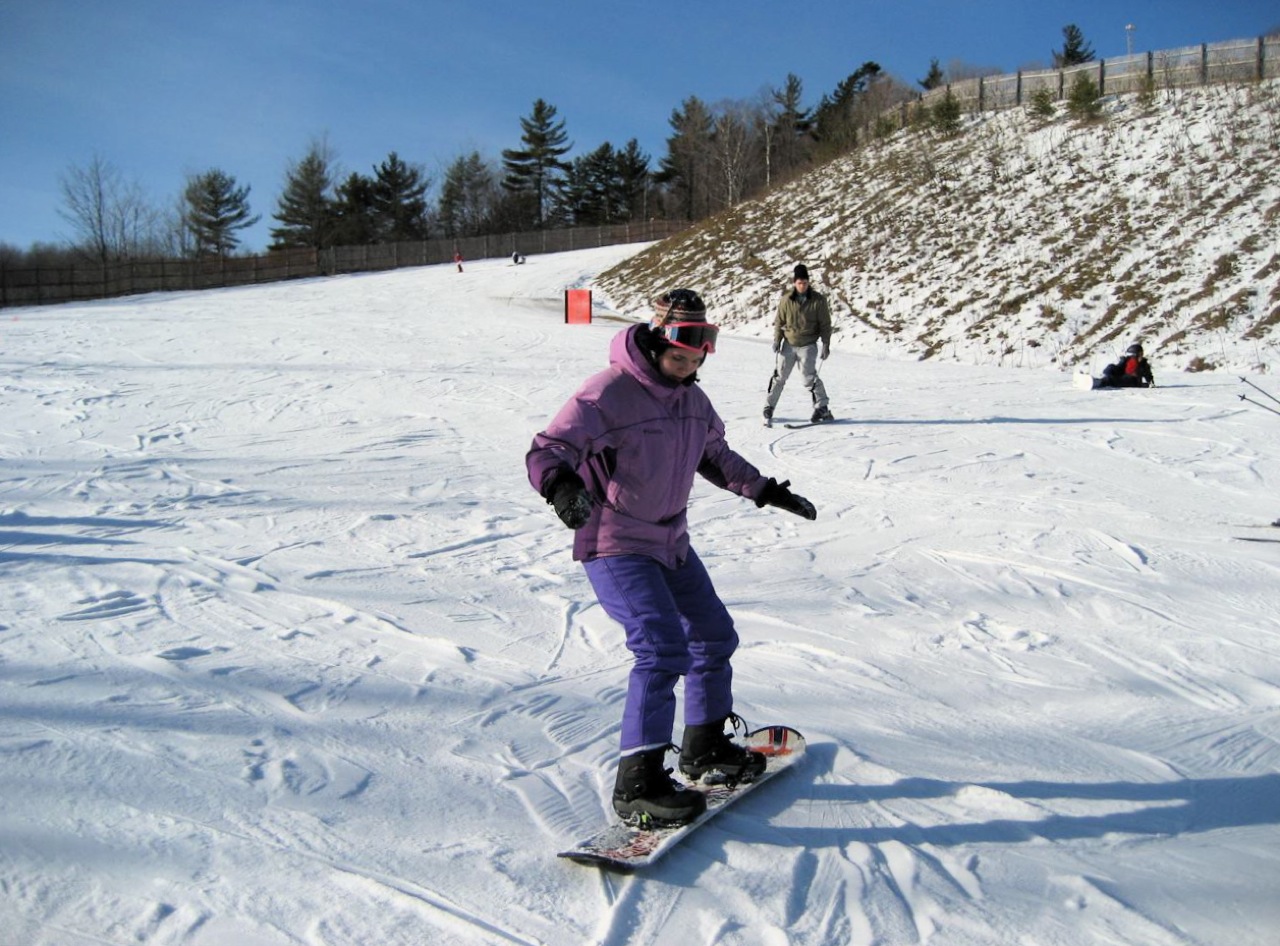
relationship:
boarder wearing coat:
[526, 289, 818, 868] [526, 323, 768, 571]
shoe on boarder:
[603, 747, 712, 826] [526, 289, 818, 868]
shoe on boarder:
[666, 712, 768, 784] [526, 289, 818, 868]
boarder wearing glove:
[526, 289, 818, 868] [729, 474, 831, 522]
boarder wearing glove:
[526, 289, 818, 868] [522, 460, 622, 536]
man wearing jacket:
[763, 264, 833, 429] [768, 286, 833, 348]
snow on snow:
[0, 239, 1280, 946] [0, 232, 1275, 937]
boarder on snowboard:
[526, 289, 818, 868] [561, 714, 805, 872]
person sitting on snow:
[1085, 316, 1168, 390] [0, 232, 1275, 937]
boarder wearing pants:
[526, 289, 818, 868] [587, 540, 740, 763]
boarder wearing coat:
[526, 289, 818, 868] [515, 318, 771, 569]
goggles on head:
[658, 325, 717, 351] [631, 286, 726, 379]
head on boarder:
[631, 286, 726, 379] [526, 289, 818, 868]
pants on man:
[764, 349, 836, 418] [750, 269, 861, 415]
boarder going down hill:
[503, 281, 849, 918] [852, 256, 1154, 884]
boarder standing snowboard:
[526, 289, 818, 868] [578, 719, 806, 891]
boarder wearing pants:
[526, 289, 818, 868] [580, 542, 756, 779]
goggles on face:
[650, 332, 726, 357] [650, 297, 722, 387]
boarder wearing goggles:
[526, 289, 818, 868] [658, 325, 717, 351]